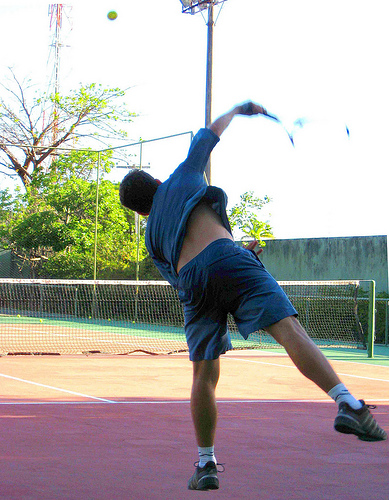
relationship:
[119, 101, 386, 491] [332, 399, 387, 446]
man has right foot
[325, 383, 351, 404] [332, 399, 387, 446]
sock on right foot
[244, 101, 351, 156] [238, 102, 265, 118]
racket in hand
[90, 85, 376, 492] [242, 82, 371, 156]
man swinging racket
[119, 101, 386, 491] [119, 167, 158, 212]
man has hair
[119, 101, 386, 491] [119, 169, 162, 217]
man has head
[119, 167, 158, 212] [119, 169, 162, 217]
hair on head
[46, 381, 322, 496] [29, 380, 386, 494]
shadow on court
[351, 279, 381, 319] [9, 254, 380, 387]
pole holding net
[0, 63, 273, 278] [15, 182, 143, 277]
leaves on tree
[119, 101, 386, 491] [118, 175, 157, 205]
man has hair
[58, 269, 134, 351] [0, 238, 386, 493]
net on court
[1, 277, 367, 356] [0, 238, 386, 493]
net on court